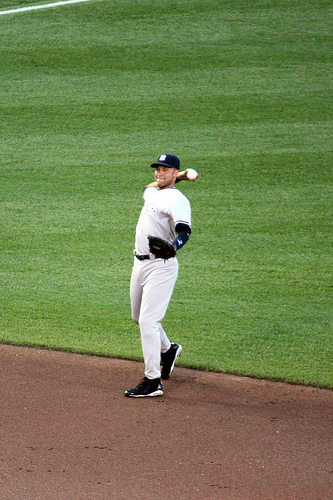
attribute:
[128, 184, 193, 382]
uniform — baseball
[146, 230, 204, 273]
glove — black, baseball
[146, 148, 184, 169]
hat — black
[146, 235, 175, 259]
glove — black, baseball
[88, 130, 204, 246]
baseball glove — black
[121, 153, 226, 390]
man — playing, defense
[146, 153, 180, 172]
hat — blue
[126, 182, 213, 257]
jersey — white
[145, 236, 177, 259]
baseball glove — black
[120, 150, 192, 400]
player — standing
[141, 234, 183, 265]
glove — black, baseball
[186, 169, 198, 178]
ball — white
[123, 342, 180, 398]
shoes — black, white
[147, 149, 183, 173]
cap — black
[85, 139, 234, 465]
man — white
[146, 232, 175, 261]
glove — Black 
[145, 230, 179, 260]
glove — black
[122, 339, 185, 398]
cleats — black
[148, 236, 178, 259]
hand — players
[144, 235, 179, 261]
hand — players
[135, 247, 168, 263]
belt — black